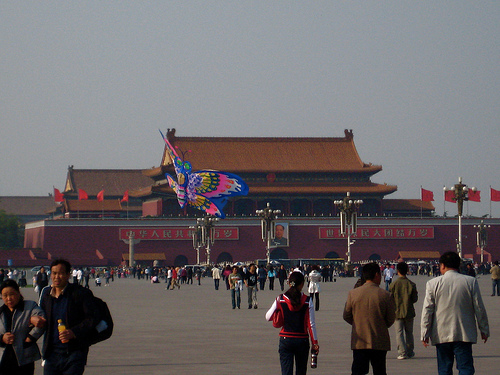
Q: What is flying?
A: Kite.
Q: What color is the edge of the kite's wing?
A: Blue.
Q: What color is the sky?
A: Gray.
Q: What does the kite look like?
A: Butterfly.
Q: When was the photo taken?
A: Daytime.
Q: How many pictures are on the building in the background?
A: One.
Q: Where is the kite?
A: In the air.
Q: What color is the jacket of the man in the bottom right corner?
A: White.